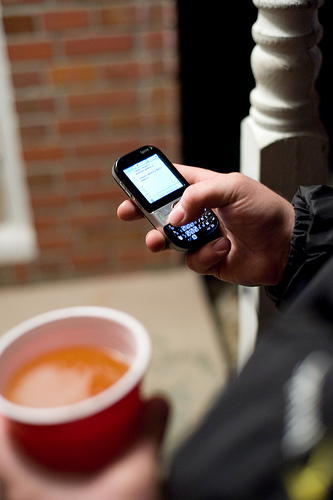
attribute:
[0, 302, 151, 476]
cup — red, white, blurry, drink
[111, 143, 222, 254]
cell phone — black, white, on, silver, cell phone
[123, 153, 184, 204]
lcd screen — on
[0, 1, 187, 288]
brick wall — blurry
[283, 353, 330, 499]
white and yellow — blurry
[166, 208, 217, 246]
buttons — lit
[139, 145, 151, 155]
word — Sprint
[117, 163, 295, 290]
right hand — fingers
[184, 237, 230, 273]
object — pinkie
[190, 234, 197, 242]
number — 0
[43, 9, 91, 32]
object — brick